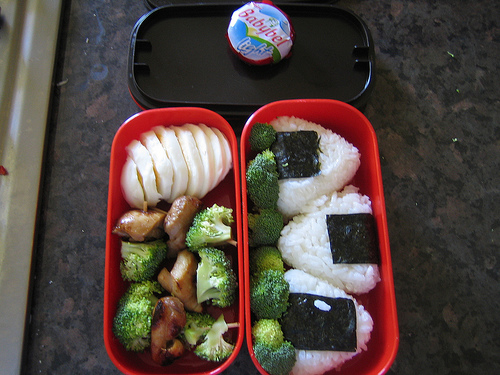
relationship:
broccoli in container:
[250, 317, 297, 375] [239, 95, 402, 375]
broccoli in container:
[250, 264, 291, 323] [239, 95, 402, 375]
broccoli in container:
[247, 202, 284, 251] [239, 95, 402, 375]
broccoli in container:
[244, 150, 283, 214] [239, 95, 402, 375]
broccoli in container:
[247, 118, 281, 156] [239, 95, 402, 375]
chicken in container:
[163, 192, 203, 259] [101, 103, 246, 375]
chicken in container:
[111, 201, 171, 249] [101, 103, 246, 375]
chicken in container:
[154, 249, 208, 318] [101, 103, 246, 375]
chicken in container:
[143, 294, 190, 366] [101, 103, 246, 375]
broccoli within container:
[247, 118, 281, 156] [239, 95, 402, 375]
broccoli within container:
[244, 150, 283, 214] [239, 95, 402, 375]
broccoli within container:
[247, 202, 284, 251] [239, 95, 402, 375]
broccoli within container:
[250, 264, 291, 323] [239, 95, 402, 375]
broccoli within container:
[250, 317, 297, 375] [239, 95, 402, 375]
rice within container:
[267, 109, 365, 218] [239, 95, 402, 375]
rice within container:
[276, 179, 383, 294] [239, 95, 402, 375]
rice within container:
[278, 264, 378, 375] [239, 95, 402, 375]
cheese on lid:
[224, 0, 298, 69] [124, 0, 379, 132]